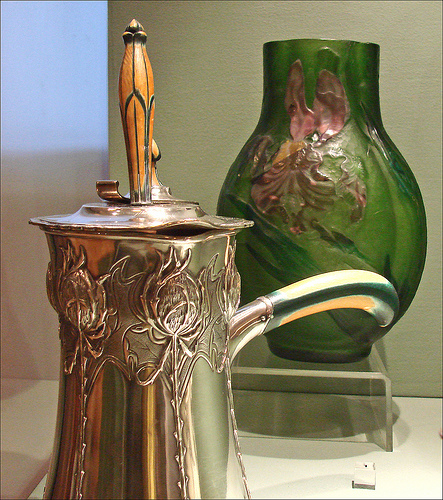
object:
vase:
[217, 36, 431, 366]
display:
[214, 23, 433, 453]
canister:
[29, 15, 400, 499]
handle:
[114, 17, 166, 207]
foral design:
[120, 245, 219, 499]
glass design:
[245, 59, 374, 240]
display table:
[2, 385, 442, 499]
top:
[34, 201, 258, 242]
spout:
[230, 256, 400, 364]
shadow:
[231, 374, 408, 464]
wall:
[105, 2, 440, 408]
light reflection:
[300, 115, 367, 187]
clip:
[353, 466, 377, 488]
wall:
[1, 1, 108, 500]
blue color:
[2, 2, 108, 152]